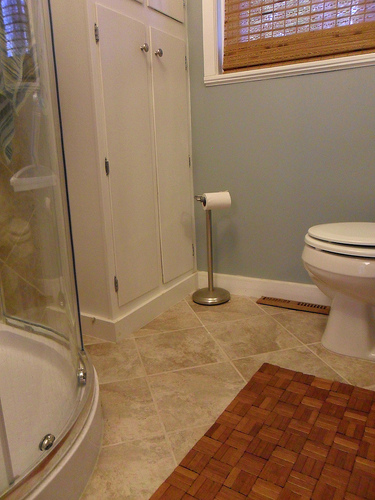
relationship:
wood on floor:
[150, 362, 375, 500] [76, 291, 374, 498]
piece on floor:
[146, 361, 374, 498] [76, 291, 374, 498]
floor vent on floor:
[254, 295, 332, 316] [20, 289, 373, 499]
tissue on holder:
[200, 190, 232, 211] [189, 188, 232, 305]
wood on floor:
[293, 402, 319, 422] [76, 291, 374, 498]